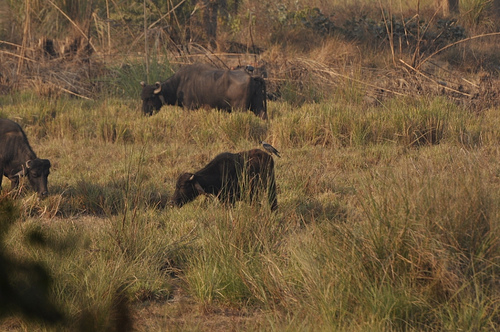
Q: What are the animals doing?
A: Eating grass.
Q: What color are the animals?
A: Brown.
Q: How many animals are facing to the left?
A: Two.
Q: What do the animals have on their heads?
A: Horns.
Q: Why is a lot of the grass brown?
A: It is dry.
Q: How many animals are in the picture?
A: Three.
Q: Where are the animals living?
A: In a grassland.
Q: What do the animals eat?
A: Grass.